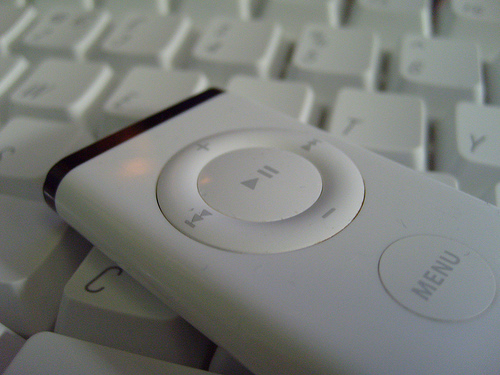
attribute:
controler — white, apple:
[41, 83, 499, 373]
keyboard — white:
[0, 1, 496, 373]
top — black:
[42, 85, 225, 210]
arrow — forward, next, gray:
[299, 131, 327, 157]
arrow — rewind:
[182, 206, 218, 235]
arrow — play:
[240, 175, 263, 193]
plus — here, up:
[196, 139, 214, 155]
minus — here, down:
[318, 203, 342, 224]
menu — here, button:
[378, 230, 497, 321]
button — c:
[49, 237, 209, 366]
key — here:
[322, 84, 432, 166]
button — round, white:
[154, 126, 365, 254]